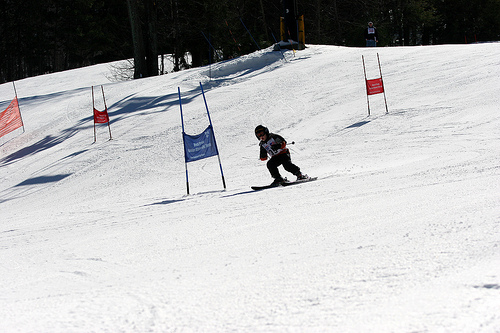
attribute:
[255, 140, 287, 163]
bib — white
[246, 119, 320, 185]
contestant — racing, downhill slaloming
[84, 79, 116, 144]
sign — red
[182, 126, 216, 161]
sign — blue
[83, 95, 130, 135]
gate — red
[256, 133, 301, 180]
clothes — black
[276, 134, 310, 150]
pole — ski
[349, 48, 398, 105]
sign — red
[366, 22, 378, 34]
bib — white